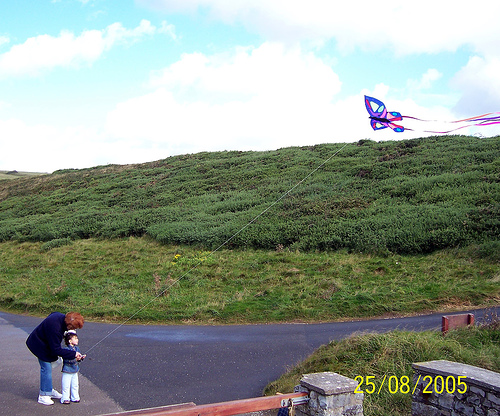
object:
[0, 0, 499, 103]
fluffy clouds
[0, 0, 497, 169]
sky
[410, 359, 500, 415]
stone wall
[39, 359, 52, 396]
blue jeans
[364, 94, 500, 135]
kite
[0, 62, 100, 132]
air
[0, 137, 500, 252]
green field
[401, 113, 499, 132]
tail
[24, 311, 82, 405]
mother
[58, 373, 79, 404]
pants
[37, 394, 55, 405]
feet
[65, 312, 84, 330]
head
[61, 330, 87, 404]
child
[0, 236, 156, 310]
grass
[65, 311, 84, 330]
hair